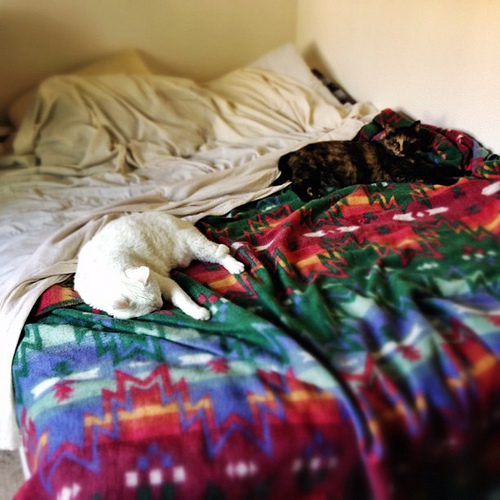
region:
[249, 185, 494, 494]
soft multi colored blanket on a bed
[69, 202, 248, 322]
an all white cat relaxes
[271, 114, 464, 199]
a tortoiseshell cat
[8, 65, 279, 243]
rumpled white bed sheets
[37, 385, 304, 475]
a zigzag blue line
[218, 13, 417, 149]
bed is placed into the corner of the room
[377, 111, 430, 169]
the tortie watches the photographer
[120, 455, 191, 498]
three white blocks between green and blue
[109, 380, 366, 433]
a yellow stripe between two orange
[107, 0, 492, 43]
cream colored walls form a corner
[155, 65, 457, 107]
the sheets match the wall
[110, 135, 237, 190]
the sheets are wrinkled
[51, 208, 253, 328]
the cat is pure white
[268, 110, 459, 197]
the cat is black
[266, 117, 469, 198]
the cat is orange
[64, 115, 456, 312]
the cats are sleeping on the bed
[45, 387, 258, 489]
the blanket is multi-colored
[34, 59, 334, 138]
the pillow is lumpy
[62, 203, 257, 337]
the cat is sleeping or playing dead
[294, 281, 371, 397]
the blanket is wrinkled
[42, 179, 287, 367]
cat is white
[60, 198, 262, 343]
cat is lying on the bed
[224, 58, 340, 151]
pillow on the bed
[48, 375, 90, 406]
pink tree on blanket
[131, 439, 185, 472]
three blue boxes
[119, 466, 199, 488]
three white boxes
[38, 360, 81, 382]
green tree on the blanket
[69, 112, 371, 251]
bed is not made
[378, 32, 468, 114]
walls are off white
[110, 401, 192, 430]
orange stripe on blanket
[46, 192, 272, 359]
A cat is on the bed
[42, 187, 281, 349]
Cat is laying down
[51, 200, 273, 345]
The cat's fur is white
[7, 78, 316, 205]
The bedsheets are white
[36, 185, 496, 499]
The blanket is multicolored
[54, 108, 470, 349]
Two cats on the bed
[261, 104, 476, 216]
Cat's fur is brown and black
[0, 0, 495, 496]
Photo was taken in the daytime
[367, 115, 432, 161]
Cat is facing the camera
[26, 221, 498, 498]
Blankets colors are red, blue, green, yellow and white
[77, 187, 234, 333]
cat is white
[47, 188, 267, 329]
cat is lounging on bed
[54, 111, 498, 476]
blanket is rainbow colored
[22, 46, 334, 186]
two pillows are on bed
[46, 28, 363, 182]
pillows are rumpled on bed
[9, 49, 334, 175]
pillows are off white color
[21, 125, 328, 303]
bedspread is pulled back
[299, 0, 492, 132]
wall is cream color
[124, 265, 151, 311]
cat's ears are pure white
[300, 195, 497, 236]
white stripe on bedcover